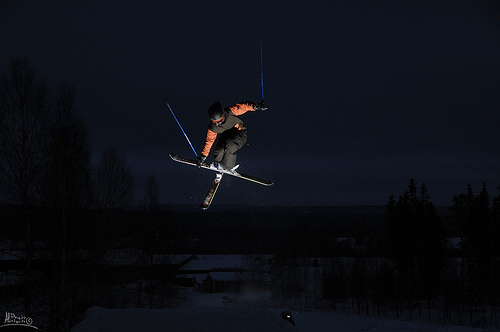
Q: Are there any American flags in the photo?
A: No, there are no American flags.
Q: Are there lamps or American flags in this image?
A: No, there are no American flags or lamps.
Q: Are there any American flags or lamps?
A: No, there are no American flags or lamps.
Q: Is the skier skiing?
A: Yes, the skier is skiing.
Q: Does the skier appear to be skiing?
A: Yes, the skier is skiing.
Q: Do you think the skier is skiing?
A: Yes, the skier is skiing.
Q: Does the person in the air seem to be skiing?
A: Yes, the skier is skiing.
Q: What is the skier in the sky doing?
A: The skier is skiing.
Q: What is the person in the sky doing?
A: The skier is skiing.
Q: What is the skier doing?
A: The skier is skiing.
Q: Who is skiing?
A: The skier is skiing.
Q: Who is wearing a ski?
A: The skier is wearing a ski.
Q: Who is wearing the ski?
A: The skier is wearing a ski.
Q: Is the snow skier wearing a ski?
A: Yes, the skier is wearing a ski.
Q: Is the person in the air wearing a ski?
A: Yes, the skier is wearing a ski.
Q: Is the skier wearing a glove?
A: No, the skier is wearing a ski.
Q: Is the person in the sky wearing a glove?
A: No, the skier is wearing a ski.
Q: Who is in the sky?
A: The skier is in the sky.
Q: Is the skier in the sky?
A: Yes, the skier is in the sky.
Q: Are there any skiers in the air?
A: Yes, there is a skier in the air.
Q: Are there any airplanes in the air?
A: No, there is a skier in the air.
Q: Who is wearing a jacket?
A: The skier is wearing a jacket.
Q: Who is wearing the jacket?
A: The skier is wearing a jacket.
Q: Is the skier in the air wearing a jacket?
A: Yes, the skier is wearing a jacket.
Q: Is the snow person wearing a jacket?
A: Yes, the skier is wearing a jacket.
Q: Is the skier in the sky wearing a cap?
A: No, the skier is wearing a jacket.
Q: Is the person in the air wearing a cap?
A: No, the skier is wearing a jacket.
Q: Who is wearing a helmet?
A: The skier is wearing a helmet.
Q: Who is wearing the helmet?
A: The skier is wearing a helmet.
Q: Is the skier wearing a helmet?
A: Yes, the skier is wearing a helmet.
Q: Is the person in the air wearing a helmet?
A: Yes, the skier is wearing a helmet.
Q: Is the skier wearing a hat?
A: No, the skier is wearing a helmet.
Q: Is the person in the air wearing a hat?
A: No, the skier is wearing a helmet.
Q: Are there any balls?
A: No, there are no balls.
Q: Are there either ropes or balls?
A: No, there are no balls or ropes.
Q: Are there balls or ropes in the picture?
A: No, there are no balls or ropes.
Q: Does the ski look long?
A: Yes, the ski is long.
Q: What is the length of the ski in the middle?
A: The ski is long.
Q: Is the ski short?
A: No, the ski is long.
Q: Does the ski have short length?
A: No, the ski is long.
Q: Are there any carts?
A: No, there are no carts.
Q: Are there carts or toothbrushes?
A: No, there are no carts or toothbrushes.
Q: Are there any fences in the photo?
A: No, there are no fences.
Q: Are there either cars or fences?
A: No, there are no fences or cars.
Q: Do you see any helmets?
A: Yes, there is a helmet.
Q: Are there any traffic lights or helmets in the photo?
A: Yes, there is a helmet.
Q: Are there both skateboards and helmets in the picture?
A: No, there is a helmet but no skateboards.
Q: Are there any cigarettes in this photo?
A: No, there are no cigarettes.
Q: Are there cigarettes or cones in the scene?
A: No, there are no cigarettes or cones.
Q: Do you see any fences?
A: No, there are no fences.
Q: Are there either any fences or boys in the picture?
A: No, there are no fences or boys.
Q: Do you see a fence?
A: No, there are no fences.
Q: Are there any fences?
A: No, there are no fences.